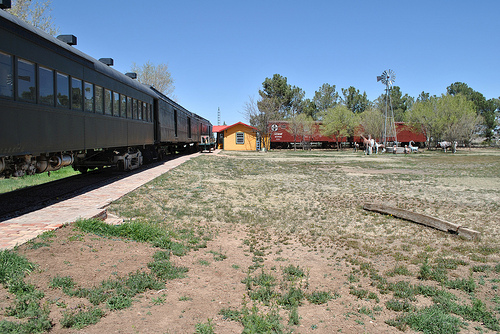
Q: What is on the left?
A: A train.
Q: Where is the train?
A: On the left.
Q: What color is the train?
A: Black.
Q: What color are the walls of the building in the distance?
A: Tan.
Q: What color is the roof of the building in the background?
A: Red.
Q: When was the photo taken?
A: Daytime.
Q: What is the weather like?
A: Totally clear.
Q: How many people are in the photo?
A: Zero.